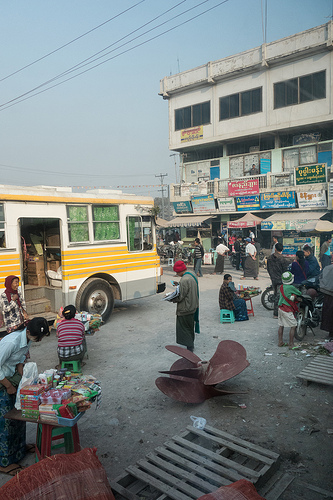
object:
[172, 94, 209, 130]
window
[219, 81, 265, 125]
window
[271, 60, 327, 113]
window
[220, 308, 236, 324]
stool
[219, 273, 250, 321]
girl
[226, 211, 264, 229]
awning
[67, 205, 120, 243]
curtains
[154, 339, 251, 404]
propeller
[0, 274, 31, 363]
person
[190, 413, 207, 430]
item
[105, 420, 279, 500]
crate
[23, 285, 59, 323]
steps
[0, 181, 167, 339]
bus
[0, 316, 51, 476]
she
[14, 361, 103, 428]
items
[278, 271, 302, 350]
child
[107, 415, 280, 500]
pallet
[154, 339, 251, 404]
fan blade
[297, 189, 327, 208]
rectangular sign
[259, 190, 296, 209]
rectangular sign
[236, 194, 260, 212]
rectangular sign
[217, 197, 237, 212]
rectangular sign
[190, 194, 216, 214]
rectangular sign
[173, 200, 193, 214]
rectangular sign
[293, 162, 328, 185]
rectangular sign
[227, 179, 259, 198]
rectangular sign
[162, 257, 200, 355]
man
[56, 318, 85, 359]
shirt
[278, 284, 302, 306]
shirt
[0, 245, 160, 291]
stripe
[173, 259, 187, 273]
cap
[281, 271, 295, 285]
hat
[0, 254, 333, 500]
ground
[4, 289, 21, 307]
scarf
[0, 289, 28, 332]
shirt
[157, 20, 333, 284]
building